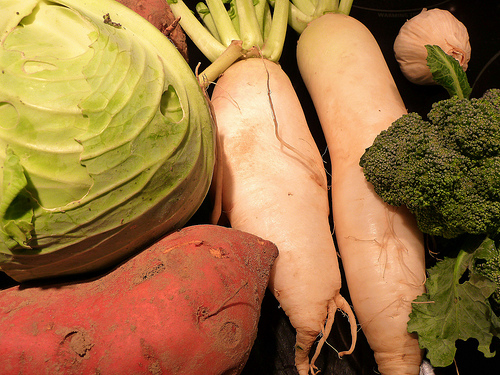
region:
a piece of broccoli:
[366, 90, 498, 227]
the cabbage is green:
[22, 35, 202, 257]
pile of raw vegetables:
[1, 1, 496, 372]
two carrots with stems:
[168, 1, 426, 374]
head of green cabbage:
[2, 2, 214, 283]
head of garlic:
[392, 6, 469, 81]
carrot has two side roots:
[171, 0, 358, 374]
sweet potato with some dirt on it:
[1, 222, 281, 367]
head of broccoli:
[354, 44, 499, 365]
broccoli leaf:
[408, 247, 496, 368]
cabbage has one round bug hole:
[1, 1, 221, 282]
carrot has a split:
[210, 56, 328, 188]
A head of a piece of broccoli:
[353, 88, 498, 244]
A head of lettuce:
[0, 0, 222, 303]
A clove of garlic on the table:
[385, 8, 483, 88]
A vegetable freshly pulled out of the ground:
[209, 37, 354, 349]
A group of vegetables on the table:
[0, 0, 499, 373]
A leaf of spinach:
[402, 245, 499, 367]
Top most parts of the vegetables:
[156, 0, 364, 71]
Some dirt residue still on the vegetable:
[137, 245, 210, 289]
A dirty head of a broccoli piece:
[340, 100, 498, 236]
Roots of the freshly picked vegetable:
[307, 293, 359, 372]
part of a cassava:
[278, 285, 317, 327]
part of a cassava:
[303, 315, 323, 329]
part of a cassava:
[286, 272, 311, 302]